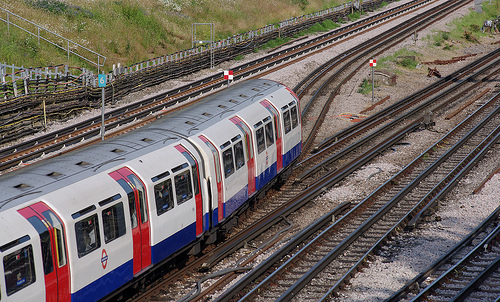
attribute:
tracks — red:
[27, 39, 492, 297]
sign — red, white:
[222, 66, 234, 86]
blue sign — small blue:
[96, 72, 110, 88]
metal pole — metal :
[100, 82, 106, 142]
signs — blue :
[96, 74, 106, 89]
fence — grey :
[0, 5, 107, 70]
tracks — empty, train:
[3, 4, 497, 300]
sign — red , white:
[367, 58, 377, 103]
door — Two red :
[197, 132, 224, 222]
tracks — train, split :
[291, 50, 358, 165]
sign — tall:
[95, 74, 107, 141]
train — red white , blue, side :
[6, 74, 301, 300]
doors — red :
[14, 98, 282, 299]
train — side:
[5, 86, 355, 288]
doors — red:
[18, 194, 73, 299]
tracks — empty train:
[286, 20, 498, 267]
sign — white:
[221, 67, 235, 87]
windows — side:
[101, 204, 131, 239]